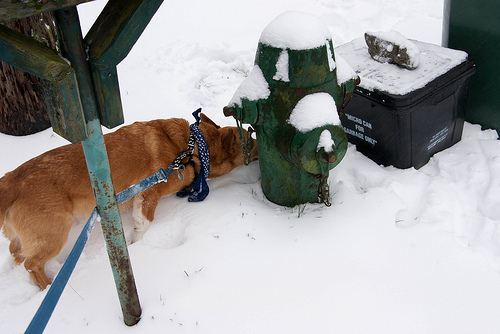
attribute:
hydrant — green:
[220, 25, 371, 211]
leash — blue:
[189, 118, 214, 203]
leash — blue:
[62, 154, 171, 283]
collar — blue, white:
[184, 123, 212, 208]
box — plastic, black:
[343, 33, 479, 174]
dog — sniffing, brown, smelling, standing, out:
[3, 109, 270, 294]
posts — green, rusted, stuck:
[41, 13, 161, 331]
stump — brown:
[1, 17, 77, 139]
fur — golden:
[38, 163, 79, 212]